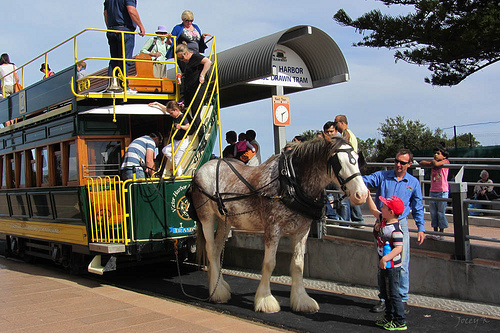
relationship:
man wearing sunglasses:
[365, 149, 428, 312] [395, 157, 408, 167]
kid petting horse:
[367, 195, 411, 331] [194, 140, 367, 314]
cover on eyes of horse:
[330, 153, 343, 174] [194, 140, 367, 314]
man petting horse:
[365, 149, 428, 312] [194, 140, 367, 314]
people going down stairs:
[167, 12, 212, 146] [163, 46, 217, 179]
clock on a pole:
[271, 96, 290, 125] [274, 123, 282, 155]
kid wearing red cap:
[367, 195, 411, 331] [380, 195, 405, 215]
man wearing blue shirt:
[365, 149, 428, 312] [366, 170, 426, 230]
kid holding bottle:
[367, 195, 411, 331] [381, 241, 392, 272]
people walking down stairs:
[167, 12, 212, 146] [163, 46, 217, 179]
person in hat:
[149, 26, 172, 60] [155, 24, 167, 34]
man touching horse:
[365, 149, 428, 312] [194, 140, 367, 314]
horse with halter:
[194, 140, 367, 314] [196, 146, 333, 241]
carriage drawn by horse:
[0, 28, 223, 281] [194, 140, 367, 314]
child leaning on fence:
[423, 150, 454, 233] [325, 159, 497, 266]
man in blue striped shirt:
[365, 149, 428, 312] [366, 170, 426, 230]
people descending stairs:
[167, 36, 215, 150] [163, 46, 217, 179]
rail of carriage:
[0, 29, 176, 101] [0, 28, 223, 281]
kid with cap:
[367, 195, 411, 331] [380, 195, 405, 215]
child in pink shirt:
[423, 150, 454, 233] [429, 159, 448, 191]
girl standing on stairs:
[164, 102, 193, 161] [163, 46, 217, 179]